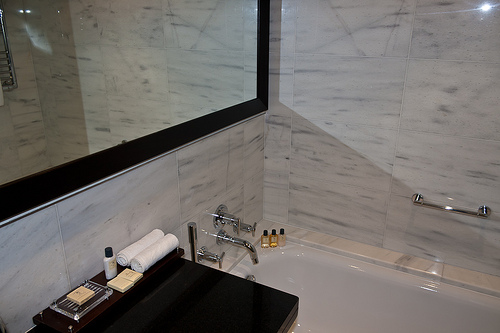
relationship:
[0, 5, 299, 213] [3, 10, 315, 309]
mirror on wall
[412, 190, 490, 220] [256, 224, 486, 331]
bar near bath tub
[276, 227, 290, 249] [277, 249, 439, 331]
bottle on tub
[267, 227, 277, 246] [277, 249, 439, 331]
bottle on tub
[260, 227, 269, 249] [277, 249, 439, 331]
bottle on tub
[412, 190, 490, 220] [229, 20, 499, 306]
bar on wall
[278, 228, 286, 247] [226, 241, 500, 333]
bottle on bath tub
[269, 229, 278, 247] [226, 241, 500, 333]
bottle on bath tub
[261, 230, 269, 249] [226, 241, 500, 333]
bottle on bath tub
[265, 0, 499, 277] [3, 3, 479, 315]
tiles on wall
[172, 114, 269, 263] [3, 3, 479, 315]
tiles on wall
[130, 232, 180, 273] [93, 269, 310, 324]
hand towel on sink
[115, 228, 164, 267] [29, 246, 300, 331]
hand towel on counter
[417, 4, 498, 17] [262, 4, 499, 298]
reflection on wall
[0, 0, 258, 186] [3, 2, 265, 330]
mirror on wall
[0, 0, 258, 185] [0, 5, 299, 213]
reflection in mirror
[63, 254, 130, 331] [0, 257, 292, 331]
soap on sink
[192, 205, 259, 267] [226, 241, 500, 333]
faucet over bath tub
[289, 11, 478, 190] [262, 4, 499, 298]
tiles on wall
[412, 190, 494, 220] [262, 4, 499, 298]
bar on wall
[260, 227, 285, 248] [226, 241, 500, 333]
soap on bath tub